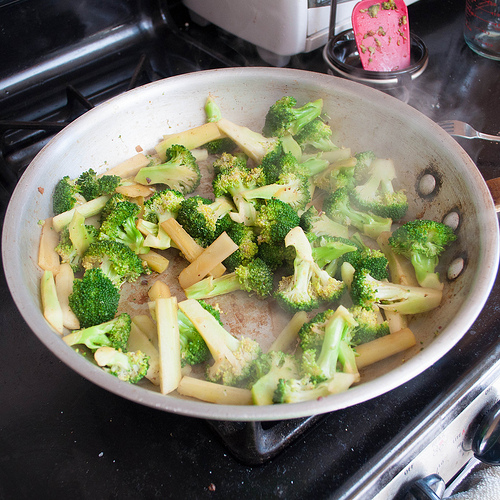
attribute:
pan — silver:
[9, 65, 499, 423]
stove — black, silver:
[1, 5, 500, 497]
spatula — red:
[353, 5, 415, 71]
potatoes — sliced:
[160, 209, 236, 284]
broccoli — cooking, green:
[139, 147, 198, 193]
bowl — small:
[328, 29, 427, 97]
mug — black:
[329, 27, 427, 100]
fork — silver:
[443, 116, 500, 144]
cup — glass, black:
[465, 3, 498, 61]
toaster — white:
[180, 3, 420, 67]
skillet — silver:
[1, 65, 500, 425]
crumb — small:
[206, 482, 216, 492]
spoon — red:
[353, 2, 412, 70]